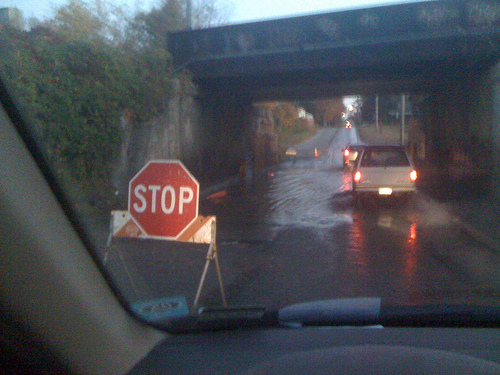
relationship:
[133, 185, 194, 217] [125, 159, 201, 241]
letters printed on stop sign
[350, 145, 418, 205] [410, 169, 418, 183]
car has tail light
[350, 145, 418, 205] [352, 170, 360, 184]
car has tail light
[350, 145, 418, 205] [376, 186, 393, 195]
car has license plate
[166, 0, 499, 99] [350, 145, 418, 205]
bridge above car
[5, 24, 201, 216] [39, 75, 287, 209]
shrub on wall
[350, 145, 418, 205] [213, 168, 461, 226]
car driving through puddle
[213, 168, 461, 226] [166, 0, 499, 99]
puddle under bridge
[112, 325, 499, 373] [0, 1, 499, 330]
dashboard in front of window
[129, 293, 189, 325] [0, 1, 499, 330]
sticker attached to window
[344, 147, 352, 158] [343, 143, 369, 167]
tail light attached to car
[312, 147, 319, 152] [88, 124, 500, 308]
traffic cone located in road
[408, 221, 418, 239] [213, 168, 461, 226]
tail light reflectio on surface of puddle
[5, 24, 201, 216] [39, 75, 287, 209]
shrub growing along wall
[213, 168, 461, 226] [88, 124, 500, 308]
puddle covering road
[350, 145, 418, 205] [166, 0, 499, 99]
car driving under bridge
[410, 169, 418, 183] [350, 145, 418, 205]
tail light mounted on car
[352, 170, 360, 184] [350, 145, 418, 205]
tail light mounted on car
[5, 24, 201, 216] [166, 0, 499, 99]
shrub growing next to bridge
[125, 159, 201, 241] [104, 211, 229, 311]
stop sign attached to barrier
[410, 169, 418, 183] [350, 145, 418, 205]
tail light on back of car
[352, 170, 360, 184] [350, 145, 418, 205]
tail light on back of car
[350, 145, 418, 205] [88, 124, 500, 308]
car driving on road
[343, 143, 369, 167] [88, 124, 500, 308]
car driving on road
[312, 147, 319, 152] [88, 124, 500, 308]
traffic cone in middle of road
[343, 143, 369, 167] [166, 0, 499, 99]
car driving under bridge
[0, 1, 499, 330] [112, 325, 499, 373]
window in front of dashboard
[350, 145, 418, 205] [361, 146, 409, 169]
car has window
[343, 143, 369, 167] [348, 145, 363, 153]
car has window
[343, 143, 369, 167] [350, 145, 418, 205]
car in front of car